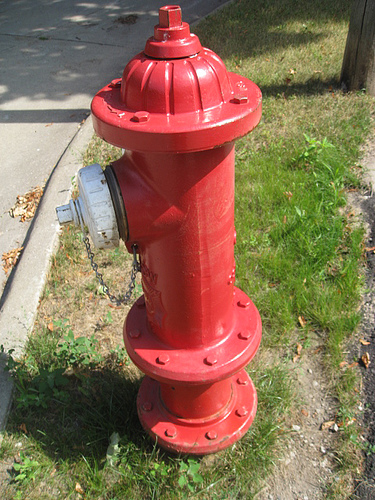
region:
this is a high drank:
[132, 18, 255, 487]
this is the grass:
[266, 171, 329, 246]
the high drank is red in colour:
[160, 19, 248, 451]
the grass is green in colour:
[269, 183, 315, 264]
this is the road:
[11, 46, 83, 93]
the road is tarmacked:
[22, 64, 90, 103]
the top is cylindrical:
[130, 69, 238, 138]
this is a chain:
[89, 254, 140, 307]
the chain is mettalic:
[86, 244, 139, 306]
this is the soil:
[294, 468, 317, 496]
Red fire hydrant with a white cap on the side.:
[55, 6, 263, 454]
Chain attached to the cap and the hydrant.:
[69, 202, 139, 305]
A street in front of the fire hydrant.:
[0, 0, 228, 311]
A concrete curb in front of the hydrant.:
[0, 2, 228, 449]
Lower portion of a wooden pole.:
[341, 0, 374, 92]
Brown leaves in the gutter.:
[0, 179, 43, 278]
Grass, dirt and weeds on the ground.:
[0, 0, 374, 498]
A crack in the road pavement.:
[1, 31, 141, 48]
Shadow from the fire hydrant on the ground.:
[0, 347, 169, 472]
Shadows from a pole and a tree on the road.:
[0, 0, 374, 123]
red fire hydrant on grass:
[45, 3, 273, 459]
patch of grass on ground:
[273, 248, 316, 309]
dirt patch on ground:
[282, 346, 318, 496]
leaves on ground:
[282, 306, 306, 366]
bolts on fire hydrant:
[152, 346, 221, 371]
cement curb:
[1, 110, 92, 435]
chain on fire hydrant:
[65, 211, 143, 312]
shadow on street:
[0, 91, 90, 148]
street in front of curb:
[3, 1, 237, 314]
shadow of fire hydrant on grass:
[1, 332, 147, 476]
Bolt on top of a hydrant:
[157, 5, 182, 25]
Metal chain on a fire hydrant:
[82, 231, 141, 308]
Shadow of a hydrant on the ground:
[0, 348, 147, 466]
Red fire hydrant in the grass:
[52, 2, 276, 454]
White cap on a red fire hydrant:
[53, 164, 124, 251]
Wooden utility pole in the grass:
[339, 0, 373, 98]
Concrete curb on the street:
[0, 114, 92, 439]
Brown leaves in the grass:
[291, 314, 306, 363]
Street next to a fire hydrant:
[0, 0, 235, 270]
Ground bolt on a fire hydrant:
[163, 427, 177, 438]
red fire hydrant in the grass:
[45, 3, 268, 441]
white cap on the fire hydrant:
[45, 163, 115, 259]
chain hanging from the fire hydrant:
[79, 231, 143, 311]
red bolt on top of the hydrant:
[156, 1, 181, 25]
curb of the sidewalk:
[5, 0, 219, 401]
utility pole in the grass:
[340, 15, 374, 86]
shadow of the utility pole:
[4, 63, 342, 124]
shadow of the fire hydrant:
[2, 339, 139, 461]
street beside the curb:
[2, 1, 138, 281]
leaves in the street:
[2, 183, 44, 288]